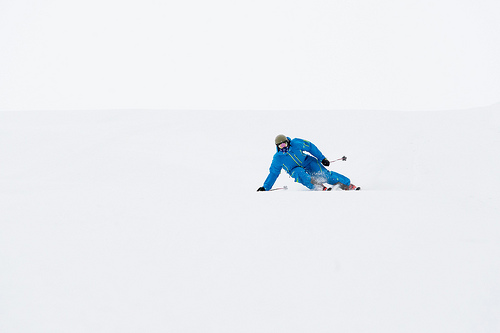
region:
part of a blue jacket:
[284, 156, 301, 171]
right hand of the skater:
[257, 176, 275, 196]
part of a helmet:
[274, 132, 286, 143]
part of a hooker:
[333, 152, 348, 165]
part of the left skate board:
[350, 181, 361, 193]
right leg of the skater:
[293, 170, 312, 187]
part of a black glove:
[321, 157, 329, 166]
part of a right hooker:
[273, 180, 293, 198]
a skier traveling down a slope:
[254, 132, 365, 202]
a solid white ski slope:
[4, 114, 495, 328]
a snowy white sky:
[2, 0, 492, 106]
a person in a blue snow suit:
[240, 126, 380, 214]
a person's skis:
[317, 179, 367, 197]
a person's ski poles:
[324, 149, 353, 170]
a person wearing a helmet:
[269, 128, 296, 152]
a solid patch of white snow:
[102, 189, 187, 261]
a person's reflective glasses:
[277, 142, 291, 153]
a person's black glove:
[319, 157, 332, 171]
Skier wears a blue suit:
[246, 116, 374, 211]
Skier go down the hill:
[237, 133, 371, 203]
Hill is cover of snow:
[5, 105, 497, 331]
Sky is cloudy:
[7, 0, 490, 110]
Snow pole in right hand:
[253, 181, 293, 198]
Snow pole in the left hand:
[320, 149, 350, 170]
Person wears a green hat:
[254, 116, 368, 210]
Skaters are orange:
[316, 176, 368, 201]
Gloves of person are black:
[246, 123, 373, 213]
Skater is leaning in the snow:
[236, 103, 374, 213]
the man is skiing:
[218, 125, 438, 255]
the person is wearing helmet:
[260, 122, 297, 155]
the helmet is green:
[267, 135, 293, 149]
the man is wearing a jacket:
[255, 134, 348, 182]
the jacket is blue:
[242, 133, 337, 189]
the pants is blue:
[287, 163, 352, 193]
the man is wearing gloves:
[221, 141, 368, 203]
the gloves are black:
[240, 150, 367, 217]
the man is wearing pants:
[272, 157, 367, 199]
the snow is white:
[299, 202, 414, 247]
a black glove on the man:
[320, 157, 330, 167]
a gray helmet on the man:
[273, 132, 288, 144]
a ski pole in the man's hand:
[256, 182, 293, 192]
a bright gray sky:
[0, 1, 499, 111]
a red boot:
[319, 182, 331, 194]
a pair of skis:
[320, 181, 364, 191]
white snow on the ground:
[1, 108, 497, 331]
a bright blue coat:
[260, 132, 330, 189]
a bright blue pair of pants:
[288, 155, 355, 189]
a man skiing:
[255, 130, 369, 193]